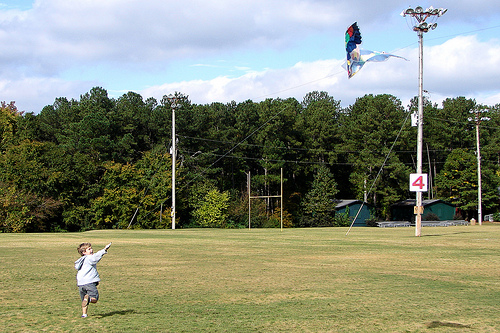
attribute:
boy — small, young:
[73, 241, 113, 318]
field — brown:
[0, 223, 499, 332]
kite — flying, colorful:
[341, 22, 413, 83]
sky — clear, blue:
[1, 0, 499, 103]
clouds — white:
[240, 35, 498, 94]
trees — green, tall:
[0, 87, 498, 232]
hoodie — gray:
[74, 252, 106, 283]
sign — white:
[409, 172, 429, 192]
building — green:
[335, 198, 371, 226]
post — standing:
[413, 32, 424, 237]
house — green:
[419, 196, 458, 222]